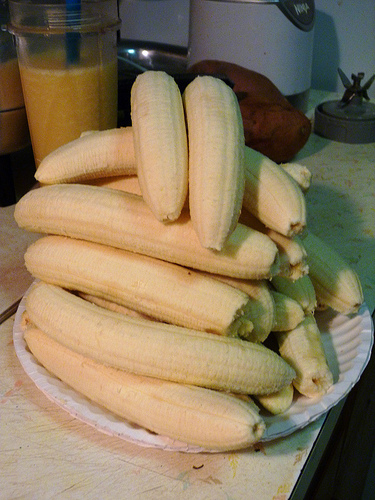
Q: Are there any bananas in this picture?
A: Yes, there is a banana.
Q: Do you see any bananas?
A: Yes, there is a banana.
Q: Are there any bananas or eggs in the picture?
A: Yes, there is a banana.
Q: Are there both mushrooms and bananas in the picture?
A: No, there is a banana but no mushrooms.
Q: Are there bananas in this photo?
A: Yes, there is a banana.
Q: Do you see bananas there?
A: Yes, there is a banana.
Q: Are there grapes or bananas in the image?
A: Yes, there is a banana.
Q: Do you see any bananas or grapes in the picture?
A: Yes, there is a banana.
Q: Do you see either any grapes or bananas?
A: Yes, there is a banana.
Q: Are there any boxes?
A: No, there are no boxes.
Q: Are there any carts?
A: No, there are no carts.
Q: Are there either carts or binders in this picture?
A: No, there are no carts or binders.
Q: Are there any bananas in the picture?
A: Yes, there is a banana.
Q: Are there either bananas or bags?
A: Yes, there is a banana.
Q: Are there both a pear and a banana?
A: No, there is a banana but no pears.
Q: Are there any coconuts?
A: No, there are no coconuts.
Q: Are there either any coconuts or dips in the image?
A: No, there are no coconuts or dips.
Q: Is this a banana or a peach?
A: This is a banana.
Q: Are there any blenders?
A: Yes, there is a blender.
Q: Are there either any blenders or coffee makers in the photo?
A: Yes, there is a blender.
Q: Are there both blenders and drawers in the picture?
A: No, there is a blender but no drawers.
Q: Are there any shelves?
A: No, there are no shelves.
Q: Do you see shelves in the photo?
A: No, there are no shelves.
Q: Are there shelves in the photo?
A: No, there are no shelves.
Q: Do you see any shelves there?
A: No, there are no shelves.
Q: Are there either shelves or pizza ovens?
A: No, there are no shelves or pizza ovens.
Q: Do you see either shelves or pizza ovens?
A: No, there are no shelves or pizza ovens.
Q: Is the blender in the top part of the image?
A: Yes, the blender is in the top of the image.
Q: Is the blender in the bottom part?
A: No, the blender is in the top of the image.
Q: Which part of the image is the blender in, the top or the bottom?
A: The blender is in the top of the image.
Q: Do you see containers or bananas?
A: Yes, there is a banana.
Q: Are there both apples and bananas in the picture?
A: No, there is a banana but no apples.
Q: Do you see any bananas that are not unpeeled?
A: Yes, there is an peeled banana.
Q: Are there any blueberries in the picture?
A: No, there are no blueberries.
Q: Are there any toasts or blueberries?
A: No, there are no blueberries or toasts.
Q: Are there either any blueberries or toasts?
A: No, there are no blueberries or toasts.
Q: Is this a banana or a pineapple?
A: This is a banana.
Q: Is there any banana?
A: Yes, there is a banana.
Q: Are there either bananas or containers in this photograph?
A: Yes, there is a banana.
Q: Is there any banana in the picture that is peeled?
A: Yes, there is a peeled banana.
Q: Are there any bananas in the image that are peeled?
A: Yes, there is a banana that is peeled.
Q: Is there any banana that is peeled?
A: Yes, there is a banana that is peeled.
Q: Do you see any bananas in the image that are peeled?
A: Yes, there is a banana that is peeled.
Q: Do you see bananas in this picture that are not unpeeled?
A: Yes, there is an peeled banana.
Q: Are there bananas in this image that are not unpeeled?
A: Yes, there is an peeled banana.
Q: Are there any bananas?
A: Yes, there is a banana.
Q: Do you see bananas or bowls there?
A: Yes, there is a banana.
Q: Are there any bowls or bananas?
A: Yes, there is a banana.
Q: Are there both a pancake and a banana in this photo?
A: No, there is a banana but no pancakes.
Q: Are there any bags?
A: No, there are no bags.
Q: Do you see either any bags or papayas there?
A: No, there are no bags or papayas.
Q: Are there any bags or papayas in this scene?
A: No, there are no bags or papayas.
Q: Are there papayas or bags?
A: No, there are no bags or papayas.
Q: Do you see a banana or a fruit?
A: Yes, there is a banana.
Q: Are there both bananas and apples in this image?
A: No, there is a banana but no apples.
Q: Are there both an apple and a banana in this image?
A: No, there is a banana but no apples.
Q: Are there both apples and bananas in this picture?
A: No, there is a banana but no apples.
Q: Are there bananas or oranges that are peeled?
A: Yes, the banana is peeled.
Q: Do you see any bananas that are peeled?
A: Yes, there is a peeled banana.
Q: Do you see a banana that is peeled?
A: Yes, there is a banana that is peeled.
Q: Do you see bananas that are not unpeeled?
A: Yes, there is an peeled banana.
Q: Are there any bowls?
A: No, there are no bowls.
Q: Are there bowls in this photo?
A: No, there are no bowls.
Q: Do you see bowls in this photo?
A: No, there are no bowls.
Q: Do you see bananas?
A: Yes, there is a banana.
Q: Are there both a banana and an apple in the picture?
A: No, there is a banana but no apples.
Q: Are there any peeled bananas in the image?
A: Yes, there is a peeled banana.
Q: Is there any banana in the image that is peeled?
A: Yes, there is a banana that is peeled.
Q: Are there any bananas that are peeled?
A: Yes, there is a banana that is peeled.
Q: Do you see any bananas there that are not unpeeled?
A: Yes, there is an peeled banana.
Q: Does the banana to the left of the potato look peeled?
A: Yes, the banana is peeled.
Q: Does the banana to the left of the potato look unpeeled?
A: No, the banana is peeled.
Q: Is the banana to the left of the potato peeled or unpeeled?
A: The banana is peeled.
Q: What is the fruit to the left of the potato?
A: The fruit is a banana.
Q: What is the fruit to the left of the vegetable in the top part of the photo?
A: The fruit is a banana.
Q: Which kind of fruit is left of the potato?
A: The fruit is a banana.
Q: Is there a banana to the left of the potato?
A: Yes, there is a banana to the left of the potato.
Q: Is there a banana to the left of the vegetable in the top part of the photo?
A: Yes, there is a banana to the left of the potato.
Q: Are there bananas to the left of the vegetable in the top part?
A: Yes, there is a banana to the left of the potato.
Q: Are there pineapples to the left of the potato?
A: No, there is a banana to the left of the potato.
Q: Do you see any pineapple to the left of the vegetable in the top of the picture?
A: No, there is a banana to the left of the potato.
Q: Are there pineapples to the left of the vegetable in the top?
A: No, there is a banana to the left of the potato.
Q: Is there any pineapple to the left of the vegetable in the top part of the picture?
A: No, there is a banana to the left of the potato.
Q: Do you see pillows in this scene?
A: No, there are no pillows.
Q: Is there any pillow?
A: No, there are no pillows.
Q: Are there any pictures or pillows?
A: No, there are no pillows or pictures.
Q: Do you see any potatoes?
A: Yes, there is a potato.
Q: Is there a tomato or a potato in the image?
A: Yes, there is a potato.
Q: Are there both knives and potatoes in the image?
A: No, there is a potato but no knives.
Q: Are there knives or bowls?
A: No, there are no bowls or knives.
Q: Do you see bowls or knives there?
A: No, there are no bowls or knives.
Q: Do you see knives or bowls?
A: No, there are no bowls or knives.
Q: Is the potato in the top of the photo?
A: Yes, the potato is in the top of the image.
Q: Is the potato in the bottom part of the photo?
A: No, the potato is in the top of the image.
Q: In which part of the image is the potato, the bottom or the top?
A: The potato is in the top of the image.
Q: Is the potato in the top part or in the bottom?
A: The potato is in the top of the image.